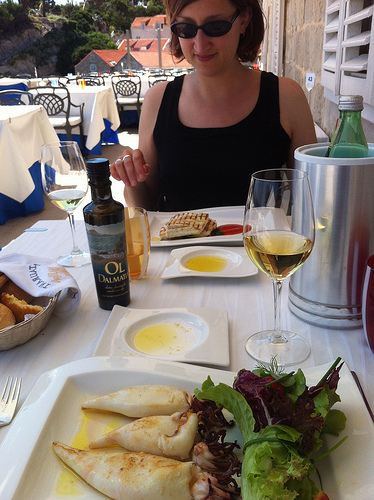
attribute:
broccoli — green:
[210, 228, 226, 236]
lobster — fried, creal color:
[49, 442, 241, 499]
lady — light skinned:
[109, 1, 320, 213]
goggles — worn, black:
[169, 7, 241, 38]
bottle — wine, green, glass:
[326, 95, 370, 157]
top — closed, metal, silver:
[338, 96, 364, 114]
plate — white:
[1, 355, 374, 499]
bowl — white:
[92, 302, 230, 366]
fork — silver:
[0, 376, 21, 426]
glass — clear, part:
[243, 168, 316, 366]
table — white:
[2, 219, 373, 444]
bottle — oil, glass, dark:
[80, 158, 131, 311]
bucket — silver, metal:
[286, 140, 374, 331]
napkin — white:
[1, 250, 80, 299]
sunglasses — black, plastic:
[169, 5, 242, 37]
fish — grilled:
[160, 210, 217, 239]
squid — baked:
[53, 383, 241, 500]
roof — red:
[74, 13, 191, 64]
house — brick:
[74, 13, 193, 73]